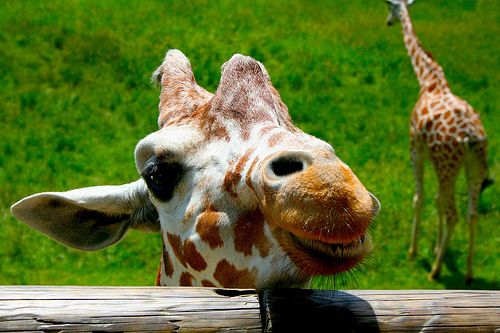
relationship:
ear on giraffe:
[3, 181, 145, 265] [7, 46, 384, 291]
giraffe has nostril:
[7, 46, 384, 291] [264, 147, 316, 182]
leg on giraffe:
[404, 150, 425, 249] [372, 0, 492, 285]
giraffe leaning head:
[381, 3, 490, 280] [12, 48, 381, 289]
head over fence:
[12, 48, 381, 289] [0, 285, 500, 331]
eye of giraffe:
[139, 158, 190, 203] [7, 46, 384, 291]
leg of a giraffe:
[429, 162, 461, 269] [372, 0, 492, 285]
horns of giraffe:
[143, 47, 292, 126] [381, 3, 490, 280]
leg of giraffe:
[467, 165, 485, 282] [381, 3, 490, 280]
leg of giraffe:
[428, 166, 455, 278] [381, 3, 490, 280]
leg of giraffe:
[434, 210, 444, 254] [381, 3, 490, 280]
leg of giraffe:
[404, 150, 420, 260] [381, 3, 490, 280]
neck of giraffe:
[395, 5, 449, 95] [372, 0, 492, 285]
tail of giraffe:
[464, 133, 491, 217] [372, 0, 492, 285]